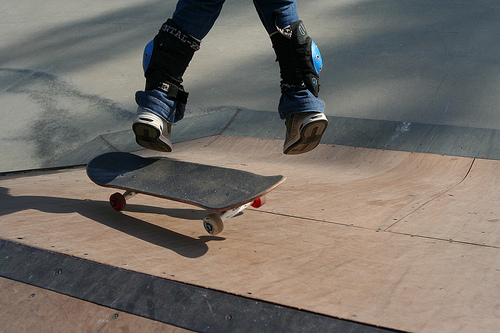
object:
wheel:
[202, 213, 223, 235]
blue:
[310, 39, 323, 76]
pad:
[143, 17, 208, 92]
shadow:
[0, 180, 226, 259]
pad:
[261, 19, 320, 100]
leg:
[249, 0, 329, 115]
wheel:
[251, 198, 267, 208]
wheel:
[109, 192, 126, 213]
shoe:
[282, 119, 328, 156]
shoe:
[127, 122, 174, 153]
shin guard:
[268, 15, 325, 99]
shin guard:
[133, 20, 208, 110]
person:
[130, 0, 331, 156]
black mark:
[381, 262, 421, 316]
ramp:
[0, 118, 498, 331]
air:
[123, 97, 331, 214]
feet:
[280, 109, 328, 155]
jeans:
[132, 1, 324, 114]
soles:
[130, 122, 172, 153]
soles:
[283, 118, 329, 157]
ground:
[2, 133, 498, 331]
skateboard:
[86, 148, 287, 237]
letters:
[160, 22, 201, 50]